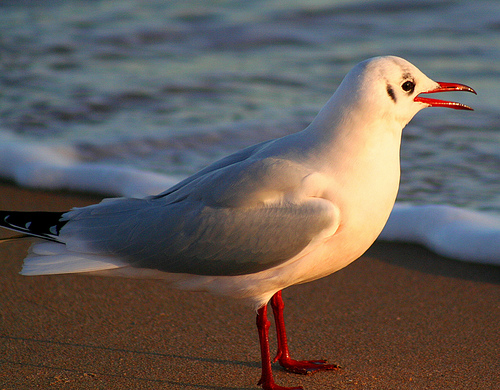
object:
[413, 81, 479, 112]
beak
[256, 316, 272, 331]
knees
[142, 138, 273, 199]
wings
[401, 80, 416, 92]
eye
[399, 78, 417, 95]
ring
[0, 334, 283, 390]
shadow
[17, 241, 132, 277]
tail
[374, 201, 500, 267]
seafoam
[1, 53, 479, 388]
bird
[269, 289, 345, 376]
leg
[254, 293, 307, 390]
leg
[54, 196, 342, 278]
wing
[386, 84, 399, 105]
spot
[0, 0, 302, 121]
water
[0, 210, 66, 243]
feathers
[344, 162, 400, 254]
chest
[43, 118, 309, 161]
wave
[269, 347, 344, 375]
feet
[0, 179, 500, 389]
beach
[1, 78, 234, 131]
waves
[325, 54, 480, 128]
head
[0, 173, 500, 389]
sand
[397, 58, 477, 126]
face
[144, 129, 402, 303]
body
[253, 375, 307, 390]
foot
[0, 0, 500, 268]
ocean